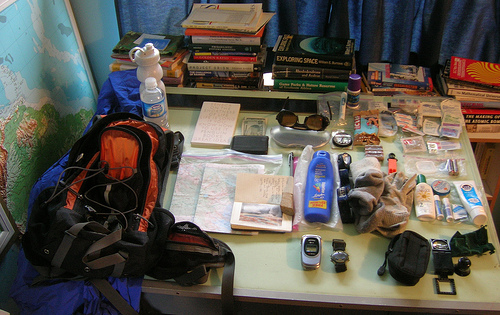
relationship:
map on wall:
[1, 1, 96, 234] [0, 2, 98, 247]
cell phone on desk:
[300, 234, 322, 272] [20, 100, 499, 312]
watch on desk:
[330, 237, 348, 270] [3, 82, 498, 312]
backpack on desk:
[32, 106, 233, 308] [88, 83, 498, 311]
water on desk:
[139, 80, 180, 130] [62, 56, 480, 270]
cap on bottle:
[140, 73, 159, 93] [139, 76, 170, 128]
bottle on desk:
[129, 42, 169, 128] [91, 97, 482, 311]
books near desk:
[105, 4, 355, 96] [72, 16, 483, 304]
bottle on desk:
[298, 149, 339, 222] [73, 52, 483, 306]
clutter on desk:
[103, 34, 467, 291] [59, 80, 484, 313]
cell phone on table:
[291, 225, 321, 277] [69, 84, 476, 307]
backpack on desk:
[20, 114, 237, 315] [73, 52, 500, 315]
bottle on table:
[139, 74, 172, 136] [69, 84, 476, 307]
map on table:
[378, 59, 425, 84] [69, 84, 476, 307]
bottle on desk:
[318, 110, 360, 145] [73, 52, 500, 315]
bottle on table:
[139, 76, 170, 128] [59, 85, 444, 305]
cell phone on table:
[300, 234, 322, 272] [69, 84, 476, 307]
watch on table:
[330, 237, 350, 273] [84, 44, 454, 308]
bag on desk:
[373, 226, 433, 282] [73, 52, 500, 315]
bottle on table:
[303, 150, 335, 224] [49, 50, 479, 300]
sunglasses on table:
[267, 92, 337, 130] [37, 59, 482, 312]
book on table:
[267, 29, 362, 70] [49, 50, 479, 300]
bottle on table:
[124, 37, 181, 136] [69, 84, 476, 307]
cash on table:
[241, 119, 265, 136] [73, 97, 483, 312]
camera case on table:
[377, 229, 431, 286] [137, 83, 494, 311]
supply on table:
[409, 162, 492, 228] [131, 63, 498, 312]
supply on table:
[410, 170, 440, 224] [137, 83, 494, 311]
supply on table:
[382, 152, 407, 183] [137, 83, 494, 311]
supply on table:
[349, 98, 385, 147] [137, 83, 494, 311]